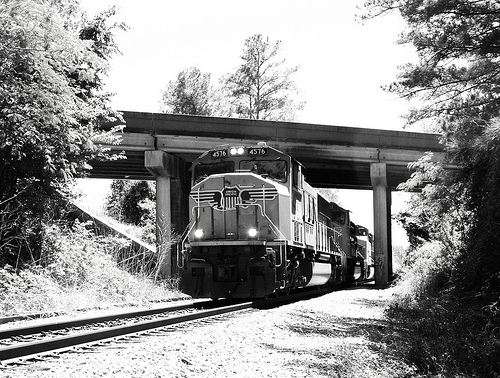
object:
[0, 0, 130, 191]
leaves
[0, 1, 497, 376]
scene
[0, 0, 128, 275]
tree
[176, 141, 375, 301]
train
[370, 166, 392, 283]
column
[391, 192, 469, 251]
leaves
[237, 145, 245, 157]
light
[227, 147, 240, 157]
light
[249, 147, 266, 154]
numbers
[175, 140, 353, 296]
train car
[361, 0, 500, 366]
tree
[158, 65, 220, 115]
tree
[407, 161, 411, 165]
leaf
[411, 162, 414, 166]
leaf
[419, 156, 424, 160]
leaf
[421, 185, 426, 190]
leaf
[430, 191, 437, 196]
leaf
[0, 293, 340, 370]
track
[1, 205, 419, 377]
ground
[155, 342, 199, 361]
gravel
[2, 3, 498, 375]
outside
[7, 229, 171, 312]
weeds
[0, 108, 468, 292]
bridge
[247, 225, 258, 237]
headlight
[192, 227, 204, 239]
headlight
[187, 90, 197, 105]
leaves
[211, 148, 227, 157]
4576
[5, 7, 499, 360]
clear day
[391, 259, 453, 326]
leaves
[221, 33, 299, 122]
tree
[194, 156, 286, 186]
windows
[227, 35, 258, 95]
leaves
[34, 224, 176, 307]
brush